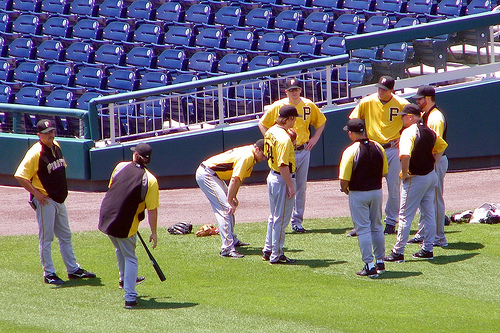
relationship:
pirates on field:
[19, 55, 467, 286] [13, 227, 425, 330]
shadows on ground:
[282, 222, 332, 280] [114, 171, 436, 308]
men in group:
[11, 112, 492, 211] [33, 110, 431, 250]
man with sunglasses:
[33, 116, 78, 291] [46, 127, 54, 136]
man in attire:
[33, 116, 78, 291] [25, 145, 75, 260]